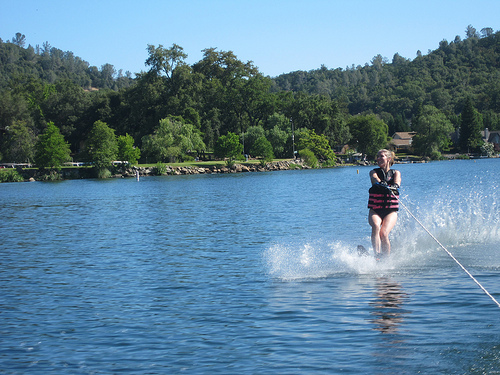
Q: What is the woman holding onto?
A: Rope.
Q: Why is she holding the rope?
A: So she can ski.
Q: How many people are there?
A: One.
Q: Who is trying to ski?
A: A woman.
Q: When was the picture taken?
A: Daytime.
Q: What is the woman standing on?
A: Skis.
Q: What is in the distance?
A: Trees.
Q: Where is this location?
A: Lake.